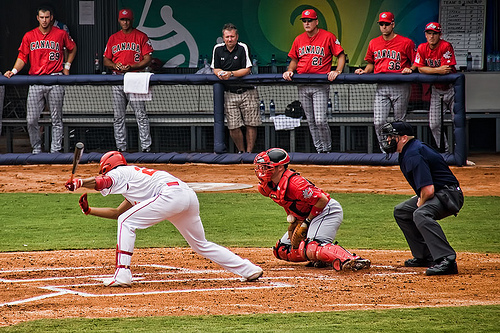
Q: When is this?
A: Daytime.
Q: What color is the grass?
A: Green.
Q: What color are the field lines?
A: White.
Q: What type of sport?
A: Baseball.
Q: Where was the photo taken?
A: Baseball field.